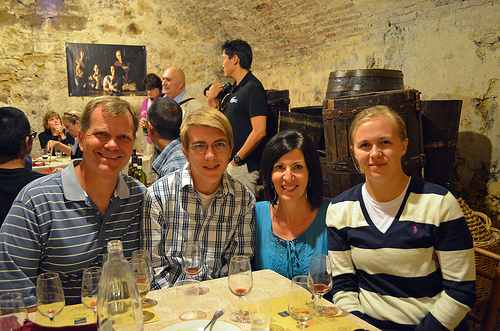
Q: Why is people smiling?
A: Taking picture.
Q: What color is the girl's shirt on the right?
A: Blue and white.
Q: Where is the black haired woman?
A: Next to girl in blue and white shirt.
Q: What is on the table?
A: Glasses.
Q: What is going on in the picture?
A: Wine tasting.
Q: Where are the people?
A: In a restaurant.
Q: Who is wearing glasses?
A: Boy in plaid shirt.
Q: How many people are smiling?
A: Four.